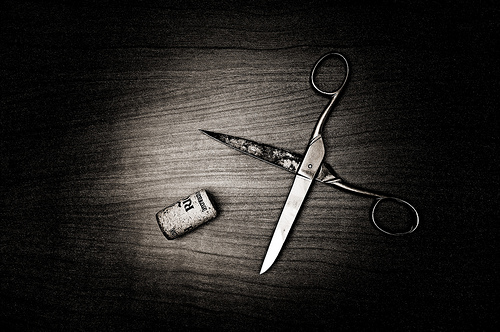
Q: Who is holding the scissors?
A: No one.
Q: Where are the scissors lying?
A: Table.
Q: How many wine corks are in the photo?
A: One.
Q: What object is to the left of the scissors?
A: Wine cork.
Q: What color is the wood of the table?
A: Brown.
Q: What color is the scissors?
A: Silver.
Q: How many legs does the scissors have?
A: Two.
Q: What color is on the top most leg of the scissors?
A: Black.